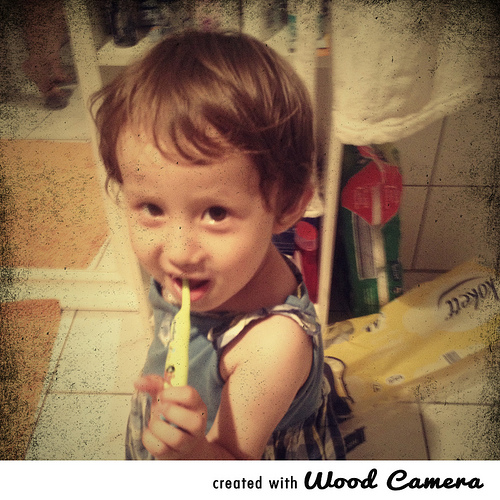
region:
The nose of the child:
[165, 240, 205, 265]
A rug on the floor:
[4, 140, 89, 263]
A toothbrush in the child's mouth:
[169, 281, 192, 388]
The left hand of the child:
[141, 385, 204, 452]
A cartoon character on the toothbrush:
[162, 363, 177, 388]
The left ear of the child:
[276, 166, 312, 230]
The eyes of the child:
[131, 199, 234, 224]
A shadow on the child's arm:
[220, 395, 236, 442]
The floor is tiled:
[73, 296, 116, 454]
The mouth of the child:
[161, 268, 219, 295]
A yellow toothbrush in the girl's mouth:
[148, 267, 219, 398]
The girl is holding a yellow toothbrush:
[132, 265, 238, 442]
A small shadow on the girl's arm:
[199, 366, 252, 464]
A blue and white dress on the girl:
[142, 295, 367, 458]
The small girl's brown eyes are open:
[135, 198, 240, 233]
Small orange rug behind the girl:
[5, 139, 117, 275]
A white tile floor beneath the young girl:
[58, 285, 133, 440]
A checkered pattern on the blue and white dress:
[142, 419, 351, 460]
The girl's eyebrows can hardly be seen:
[122, 184, 252, 204]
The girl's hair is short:
[95, 26, 334, 207]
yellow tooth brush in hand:
[136, 277, 201, 459]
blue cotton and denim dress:
[128, 279, 359, 464]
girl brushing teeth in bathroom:
[88, 28, 368, 467]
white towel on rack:
[334, 4, 484, 139]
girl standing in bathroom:
[88, 27, 364, 465]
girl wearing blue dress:
[91, 31, 363, 465]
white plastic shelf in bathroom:
[67, 4, 335, 315]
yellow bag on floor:
[330, 257, 499, 398]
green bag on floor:
[343, 145, 403, 315]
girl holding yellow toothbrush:
[91, 29, 366, 463]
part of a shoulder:
[262, 319, 304, 379]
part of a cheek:
[227, 239, 252, 266]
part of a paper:
[383, 317, 417, 379]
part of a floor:
[105, 369, 137, 414]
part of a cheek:
[214, 222, 237, 296]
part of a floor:
[66, 336, 113, 408]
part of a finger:
[156, 373, 186, 405]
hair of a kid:
[236, 98, 263, 136]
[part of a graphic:
[343, 468, 368, 483]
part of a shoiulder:
[253, 339, 290, 419]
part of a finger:
[181, 405, 211, 434]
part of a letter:
[361, 470, 374, 487]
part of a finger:
[178, 385, 195, 403]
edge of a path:
[38, 349, 57, 389]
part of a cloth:
[190, 350, 234, 402]